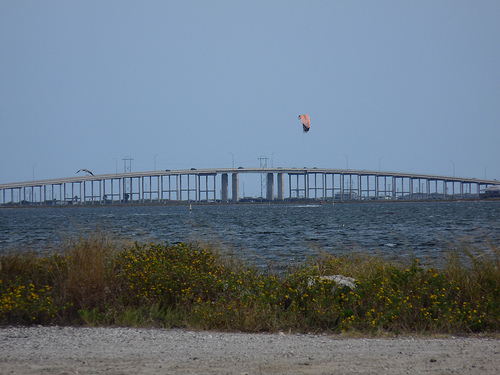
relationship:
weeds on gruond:
[205, 273, 433, 330] [177, 318, 412, 367]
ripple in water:
[256, 219, 371, 249] [2, 200, 499, 270]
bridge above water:
[1, 165, 498, 198] [2, 200, 499, 270]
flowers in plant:
[335, 265, 488, 331] [359, 257, 497, 333]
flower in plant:
[17, 285, 24, 292] [3, 274, 264, 329]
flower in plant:
[30, 290, 40, 300] [3, 274, 264, 329]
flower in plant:
[9, 297, 13, 303] [3, 274, 264, 329]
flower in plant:
[40, 291, 47, 298] [3, 274, 264, 329]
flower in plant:
[17, 285, 26, 290] [3, 274, 264, 329]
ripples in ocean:
[202, 210, 253, 229] [3, 196, 498, 260]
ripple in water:
[127, 207, 495, 214] [4, 192, 496, 281]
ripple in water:
[1, 215, 120, 227] [4, 192, 496, 281]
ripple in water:
[437, 228, 494, 237] [4, 192, 496, 281]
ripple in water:
[394, 216, 498, 234] [4, 192, 496, 281]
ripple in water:
[252, 235, 387, 241] [4, 192, 496, 281]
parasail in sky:
[295, 116, 315, 131] [1, 1, 499, 198]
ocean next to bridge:
[3, 196, 498, 260] [0, 153, 496, 205]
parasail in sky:
[297, 114, 310, 134] [1, 1, 499, 198]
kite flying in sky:
[297, 113, 310, 132] [1, 1, 499, 198]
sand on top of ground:
[2, 326, 498, 371] [2, 248, 494, 370]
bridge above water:
[1, 165, 498, 205] [43, 205, 255, 237]